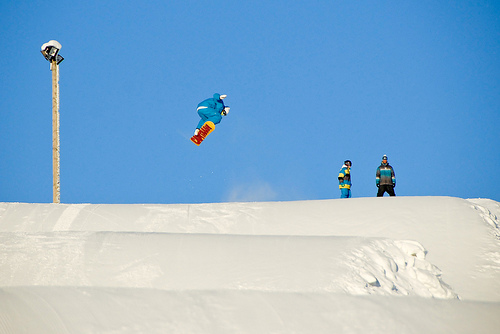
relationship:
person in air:
[187, 86, 237, 144] [236, 67, 282, 94]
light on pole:
[40, 34, 72, 68] [45, 63, 58, 213]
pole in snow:
[51, 60, 61, 204] [61, 239, 91, 278]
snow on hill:
[61, 239, 91, 278] [24, 205, 457, 318]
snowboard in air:
[192, 121, 217, 149] [236, 67, 282, 94]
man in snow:
[340, 156, 353, 193] [61, 239, 91, 278]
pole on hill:
[51, 60, 61, 204] [24, 205, 457, 318]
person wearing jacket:
[187, 86, 237, 144] [196, 91, 225, 120]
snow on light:
[61, 239, 91, 278] [40, 34, 72, 68]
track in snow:
[376, 247, 418, 299] [61, 239, 91, 278]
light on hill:
[40, 34, 72, 68] [24, 205, 457, 318]